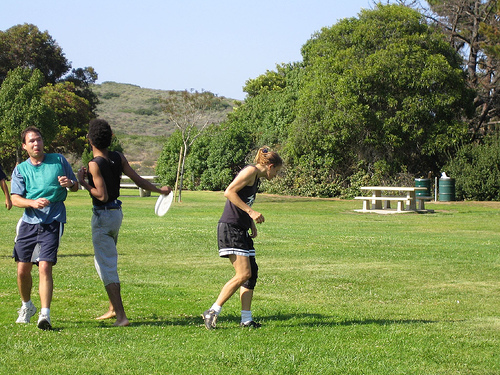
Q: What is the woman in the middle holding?
A: A frisbee.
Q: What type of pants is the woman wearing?
A: Capris.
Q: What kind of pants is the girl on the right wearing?
A: Shorts.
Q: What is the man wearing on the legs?
A: Striped shorts.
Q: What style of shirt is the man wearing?
A: T-shirt.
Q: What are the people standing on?
A: Grass.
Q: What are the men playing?
A: Frisbee.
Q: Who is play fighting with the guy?
A: A woman.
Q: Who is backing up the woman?
A: A man.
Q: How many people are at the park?
A: Three.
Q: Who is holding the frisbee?
A: A man.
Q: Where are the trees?
A: On the side.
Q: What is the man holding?
A: A frisbee.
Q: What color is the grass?
A: Green.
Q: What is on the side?
A: A bench.